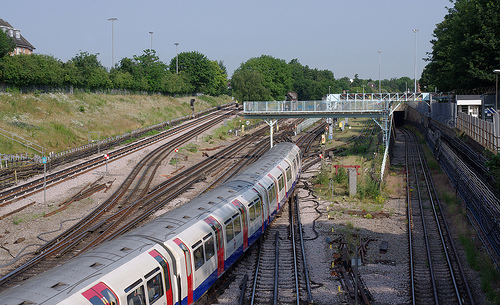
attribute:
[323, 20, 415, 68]
sky — blue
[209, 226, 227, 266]
door — red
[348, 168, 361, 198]
pole — small, grey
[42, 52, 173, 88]
trees — several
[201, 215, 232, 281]
door — red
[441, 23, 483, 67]
green tree — thick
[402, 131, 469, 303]
track — train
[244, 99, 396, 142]
bridge — small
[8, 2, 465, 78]
sky — blue, clear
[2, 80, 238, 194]
hill — sloping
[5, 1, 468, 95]
sky — blue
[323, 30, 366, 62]
clouds — white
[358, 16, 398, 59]
clouds — white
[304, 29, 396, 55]
clouds — white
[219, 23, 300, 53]
clouds — white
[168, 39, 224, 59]
clouds — white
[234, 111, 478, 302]
tracks — train